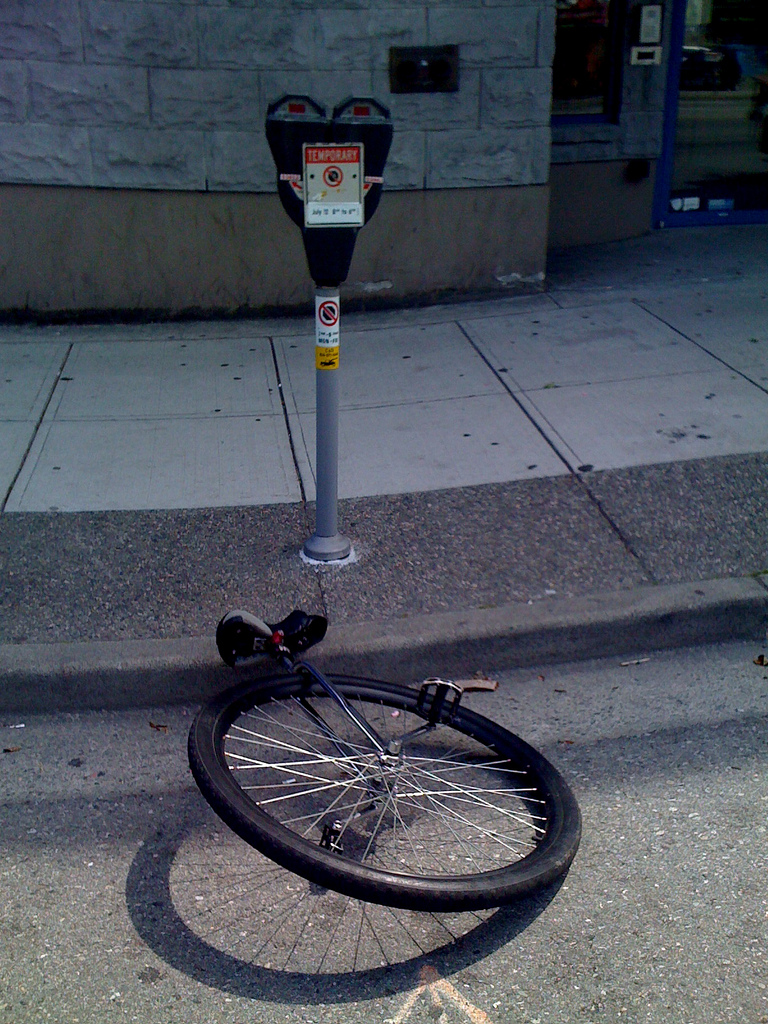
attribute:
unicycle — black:
[177, 600, 625, 936]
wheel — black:
[218, 736, 617, 874]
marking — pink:
[338, 980, 491, 1020]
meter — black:
[265, 128, 371, 239]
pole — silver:
[279, 311, 383, 502]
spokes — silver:
[272, 715, 433, 802]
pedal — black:
[401, 681, 468, 736]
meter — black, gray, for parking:
[267, 93, 394, 555]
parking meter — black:
[255, 86, 404, 274]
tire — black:
[171, 650, 589, 918]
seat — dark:
[199, 596, 352, 665]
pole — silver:
[303, 294, 354, 562]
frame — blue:
[653, 1, 764, 234]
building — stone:
[6, 0, 641, 316]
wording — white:
[303, 149, 361, 167]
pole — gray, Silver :
[295, 289, 355, 564]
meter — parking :
[252, 83, 391, 293]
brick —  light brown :
[6, 187, 538, 298]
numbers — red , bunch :
[277, 103, 376, 119]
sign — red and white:
[308, 297, 341, 336]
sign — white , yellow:
[303, 300, 347, 374]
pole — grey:
[305, 367, 366, 570]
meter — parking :
[253, 80, 401, 565]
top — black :
[627, 885, 699, 995]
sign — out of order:
[308, 141, 361, 224]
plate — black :
[383, 41, 472, 106]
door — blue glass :
[653, 8, 742, 232]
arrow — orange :
[397, 967, 522, 1018]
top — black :
[622, 867, 718, 1013]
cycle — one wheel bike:
[168, 684, 616, 924]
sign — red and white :
[298, 145, 362, 223]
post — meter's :
[299, 280, 371, 569]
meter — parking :
[270, 69, 411, 563]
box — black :
[375, 34, 481, 89]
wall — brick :
[3, 2, 546, 292]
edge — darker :
[482, 632, 610, 654]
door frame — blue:
[666, 0, 763, 234]